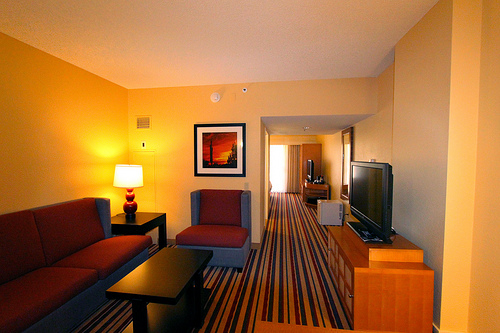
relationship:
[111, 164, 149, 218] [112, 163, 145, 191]
lamp has lampshade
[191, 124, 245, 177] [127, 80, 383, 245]
catus photograph hung on wall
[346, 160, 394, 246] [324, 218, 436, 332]
television set on top of dresser drawer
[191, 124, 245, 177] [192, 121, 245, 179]
catus photograph has frame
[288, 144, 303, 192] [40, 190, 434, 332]
curtain hangs to flooring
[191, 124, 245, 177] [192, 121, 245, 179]
catus photograph inside frame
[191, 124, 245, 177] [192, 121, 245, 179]
catus photograph in frame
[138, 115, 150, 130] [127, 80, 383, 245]
air vent on side of wall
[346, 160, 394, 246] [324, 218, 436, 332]
television set atop dresser drawer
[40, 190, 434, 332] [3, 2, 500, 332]
flooring in hotel room